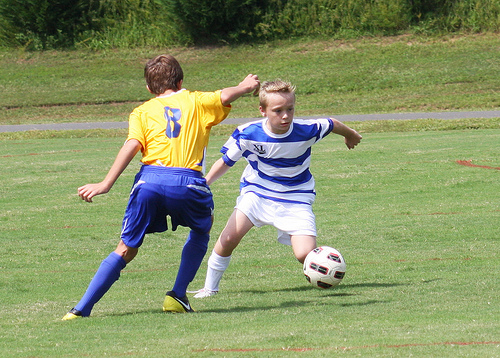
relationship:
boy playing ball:
[58, 51, 261, 322] [300, 243, 349, 291]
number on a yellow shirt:
[163, 106, 183, 140] [125, 89, 233, 169]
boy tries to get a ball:
[62, 54, 260, 320] [301, 237, 356, 295]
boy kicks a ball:
[190, 77, 364, 301] [302, 244, 344, 289]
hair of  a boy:
[142, 52, 185, 98] [62, 54, 260, 320]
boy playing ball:
[190, 77, 364, 301] [300, 243, 349, 291]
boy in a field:
[58, 51, 261, 322] [13, 114, 497, 354]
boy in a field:
[190, 77, 364, 301] [13, 114, 497, 354]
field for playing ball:
[13, 114, 497, 354] [300, 243, 349, 291]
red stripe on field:
[191, 339, 500, 353] [0, 29, 499, 357]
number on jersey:
[160, 106, 190, 146] [134, 99, 216, 176]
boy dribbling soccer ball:
[197, 81, 361, 291] [300, 240, 345, 290]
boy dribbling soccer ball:
[62, 54, 260, 320] [300, 240, 345, 290]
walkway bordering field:
[0, 105, 499, 136] [3, 37, 495, 354]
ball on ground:
[300, 243, 352, 293] [1, 128, 497, 356]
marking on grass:
[449, 148, 495, 183] [396, 125, 493, 293]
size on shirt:
[250, 135, 270, 160] [222, 116, 331, 206]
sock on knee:
[204, 250, 231, 293] [219, 220, 237, 251]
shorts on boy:
[118, 165, 215, 247] [62, 54, 260, 320]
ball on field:
[300, 243, 349, 291] [347, 148, 476, 338]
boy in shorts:
[197, 81, 361, 291] [240, 191, 312, 242]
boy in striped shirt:
[197, 81, 361, 291] [217, 116, 336, 207]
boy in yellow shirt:
[62, 54, 260, 320] [125, 87, 233, 171]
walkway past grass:
[1, 103, 498, 138] [0, 114, 498, 354]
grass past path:
[286, 54, 469, 84] [6, 106, 494, 133]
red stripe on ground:
[452, 151, 497, 176] [1, 128, 497, 356]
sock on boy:
[198, 250, 226, 293] [189, 77, 359, 301]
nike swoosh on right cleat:
[172, 296, 193, 309] [155, 275, 196, 313]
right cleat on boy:
[155, 275, 196, 313] [62, 62, 197, 303]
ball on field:
[300, 243, 349, 291] [13, 114, 497, 354]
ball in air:
[300, 243, 349, 291] [77, 117, 442, 304]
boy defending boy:
[62, 54, 260, 320] [190, 77, 364, 301]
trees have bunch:
[1, 4, 496, 38] [52, 7, 477, 51]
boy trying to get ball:
[197, 81, 361, 291] [297, 246, 351, 293]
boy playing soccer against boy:
[58, 51, 261, 322] [197, 81, 361, 291]